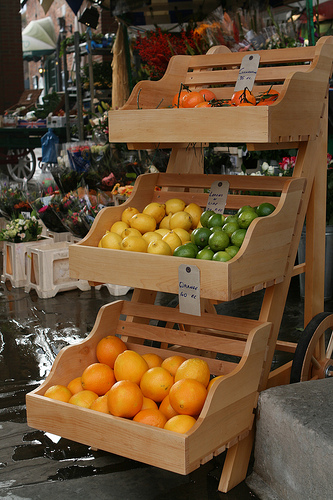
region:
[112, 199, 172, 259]
yellow lemons are visible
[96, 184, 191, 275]
yellow lemons are visible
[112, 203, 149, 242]
yellow lemons are visible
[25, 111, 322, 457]
wood display with trays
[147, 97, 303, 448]
three wood trays on display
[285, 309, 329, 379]
wheel on wood display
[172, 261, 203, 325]
tag on front of display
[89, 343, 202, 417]
oranges in wood display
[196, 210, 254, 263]
pile of limes in tray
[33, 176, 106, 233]
flower bouquets in plastic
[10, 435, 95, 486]
puddle on store floor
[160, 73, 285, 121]
tomatos in top tray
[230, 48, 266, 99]
tag on back of tray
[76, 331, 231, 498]
bulk of yummy orange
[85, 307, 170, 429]
bulk of yummy orange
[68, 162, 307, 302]
the shelf with lemons and limes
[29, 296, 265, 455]
the bottom shelf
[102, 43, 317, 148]
the top shelf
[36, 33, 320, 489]
a wooden cart on wheels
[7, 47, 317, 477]
a cart with three shelves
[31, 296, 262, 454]
a shelf full of oranges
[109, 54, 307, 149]
a shelf full of tangerines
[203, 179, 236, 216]
a price tag for the lemons and limes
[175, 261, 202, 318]
a price tag for the oranges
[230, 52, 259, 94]
The price tag for the Clementines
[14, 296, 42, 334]
this is the floor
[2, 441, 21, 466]
the floor is wooden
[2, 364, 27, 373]
the floor is wet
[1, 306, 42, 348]
this is some water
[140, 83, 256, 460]
this is a shelf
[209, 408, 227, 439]
the shelf is wooden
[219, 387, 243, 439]
the shelf is brown in color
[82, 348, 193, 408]
these are some oranges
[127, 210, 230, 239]
these are some lemons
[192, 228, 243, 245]
the lemons are green in color